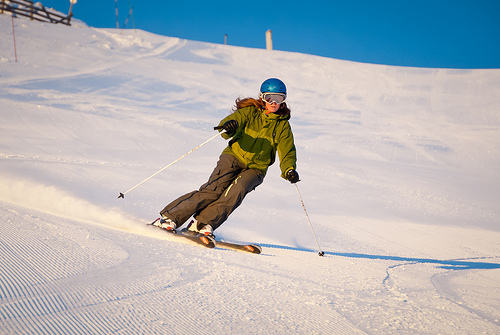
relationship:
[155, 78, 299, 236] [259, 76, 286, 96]
woman wearing helmet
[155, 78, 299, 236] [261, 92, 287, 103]
woman wearing goggles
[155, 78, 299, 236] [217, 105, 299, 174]
woman wearing jacket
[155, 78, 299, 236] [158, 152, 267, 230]
woman wearing pants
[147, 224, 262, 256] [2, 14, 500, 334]
skis in snow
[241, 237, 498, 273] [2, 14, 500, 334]
shadow on snow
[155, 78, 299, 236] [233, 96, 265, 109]
woman has hair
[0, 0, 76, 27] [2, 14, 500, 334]
fence on snow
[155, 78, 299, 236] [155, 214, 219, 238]
woman wearing boots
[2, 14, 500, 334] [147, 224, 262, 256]
snow under skis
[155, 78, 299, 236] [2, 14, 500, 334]
woman skiing on snow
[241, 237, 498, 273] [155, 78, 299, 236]
shadow of woman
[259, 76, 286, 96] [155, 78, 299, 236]
helmet on woman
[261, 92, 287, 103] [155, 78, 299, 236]
goggles on woman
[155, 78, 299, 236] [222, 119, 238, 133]
woman wearing glove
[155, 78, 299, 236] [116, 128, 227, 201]
woman holding ski pole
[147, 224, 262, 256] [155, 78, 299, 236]
skis under woman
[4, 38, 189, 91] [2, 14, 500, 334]
tracks on snow